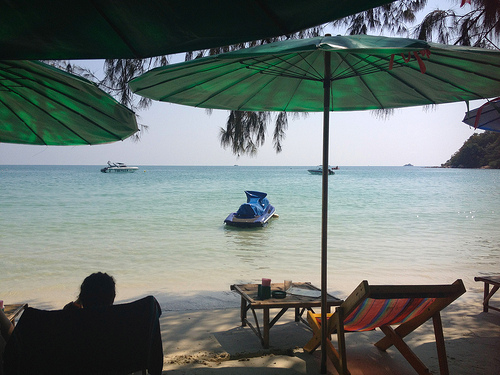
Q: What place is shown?
A: It is an ocean.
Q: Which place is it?
A: It is an ocean.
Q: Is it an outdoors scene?
A: Yes, it is outdoors.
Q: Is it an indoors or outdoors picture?
A: It is outdoors.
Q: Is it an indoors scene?
A: No, it is outdoors.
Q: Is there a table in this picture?
A: Yes, there is a table.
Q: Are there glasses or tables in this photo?
A: Yes, there is a table.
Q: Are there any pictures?
A: No, there are no pictures.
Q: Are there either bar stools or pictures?
A: No, there are no pictures or bar stools.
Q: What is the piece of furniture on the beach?
A: The piece of furniture is a table.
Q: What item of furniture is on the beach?
A: The piece of furniture is a table.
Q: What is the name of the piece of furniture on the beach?
A: The piece of furniture is a table.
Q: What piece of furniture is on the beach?
A: The piece of furniture is a table.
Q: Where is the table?
A: The table is on the beach.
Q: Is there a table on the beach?
A: Yes, there is a table on the beach.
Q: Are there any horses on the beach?
A: No, there is a table on the beach.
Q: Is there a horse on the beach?
A: No, there is a table on the beach.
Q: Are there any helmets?
A: No, there are no helmets.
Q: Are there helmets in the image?
A: No, there are no helmets.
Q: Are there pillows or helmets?
A: No, there are no helmets or pillows.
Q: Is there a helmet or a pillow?
A: No, there are no helmets or pillows.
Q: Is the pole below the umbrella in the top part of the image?
A: Yes, the pole is below the umbrella.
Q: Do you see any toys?
A: No, there are no toys.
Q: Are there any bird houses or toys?
A: No, there are no toys or bird houses.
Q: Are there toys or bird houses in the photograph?
A: No, there are no toys or bird houses.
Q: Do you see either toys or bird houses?
A: No, there are no toys or bird houses.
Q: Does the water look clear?
A: Yes, the water is clear.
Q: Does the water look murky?
A: No, the water is clear.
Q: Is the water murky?
A: No, the water is clear.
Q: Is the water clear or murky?
A: The water is clear.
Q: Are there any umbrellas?
A: Yes, there is an umbrella.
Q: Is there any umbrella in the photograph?
A: Yes, there is an umbrella.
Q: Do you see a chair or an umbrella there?
A: Yes, there is an umbrella.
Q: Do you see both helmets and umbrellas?
A: No, there is an umbrella but no helmets.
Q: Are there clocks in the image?
A: No, there are no clocks.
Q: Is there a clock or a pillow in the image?
A: No, there are no clocks or pillows.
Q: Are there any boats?
A: Yes, there is a boat.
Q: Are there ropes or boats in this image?
A: Yes, there is a boat.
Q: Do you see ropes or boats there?
A: Yes, there is a boat.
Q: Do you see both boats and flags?
A: No, there is a boat but no flags.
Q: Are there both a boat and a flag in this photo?
A: No, there is a boat but no flags.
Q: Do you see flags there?
A: No, there are no flags.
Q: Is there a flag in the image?
A: No, there are no flags.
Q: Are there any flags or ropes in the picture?
A: No, there are no flags or ropes.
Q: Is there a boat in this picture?
A: Yes, there is a boat.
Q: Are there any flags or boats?
A: Yes, there is a boat.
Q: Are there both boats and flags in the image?
A: No, there is a boat but no flags.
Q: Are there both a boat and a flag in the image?
A: No, there is a boat but no flags.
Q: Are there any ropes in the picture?
A: No, there are no ropes.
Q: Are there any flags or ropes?
A: No, there are no ropes or flags.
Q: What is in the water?
A: The boat is in the water.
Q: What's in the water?
A: The boat is in the water.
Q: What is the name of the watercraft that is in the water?
A: The watercraft is a boat.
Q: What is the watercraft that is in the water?
A: The watercraft is a boat.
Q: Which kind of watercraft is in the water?
A: The watercraft is a boat.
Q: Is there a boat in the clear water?
A: Yes, there is a boat in the water.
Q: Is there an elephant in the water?
A: No, there is a boat in the water.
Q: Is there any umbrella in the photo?
A: Yes, there is an umbrella.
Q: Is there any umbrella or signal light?
A: Yes, there is an umbrella.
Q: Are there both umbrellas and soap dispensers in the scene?
A: No, there is an umbrella but no soap dispensers.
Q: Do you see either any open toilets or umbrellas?
A: Yes, there is an open umbrella.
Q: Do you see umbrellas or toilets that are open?
A: Yes, the umbrella is open.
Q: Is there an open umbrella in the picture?
A: Yes, there is an open umbrella.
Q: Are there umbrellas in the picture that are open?
A: Yes, there is an umbrella that is open.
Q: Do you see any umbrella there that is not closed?
A: Yes, there is a open umbrella.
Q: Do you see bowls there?
A: No, there are no bowls.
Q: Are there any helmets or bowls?
A: No, there are no bowls or helmets.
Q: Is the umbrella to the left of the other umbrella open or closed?
A: The umbrella is open.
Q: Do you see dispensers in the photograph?
A: No, there are no dispensers.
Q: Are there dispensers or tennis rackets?
A: No, there are no dispensers or tennis rackets.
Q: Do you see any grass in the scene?
A: Yes, there is grass.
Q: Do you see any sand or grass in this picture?
A: Yes, there is grass.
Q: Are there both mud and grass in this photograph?
A: No, there is grass but no mud.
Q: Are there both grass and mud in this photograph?
A: No, there is grass but no mud.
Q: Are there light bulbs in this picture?
A: No, there are no light bulbs.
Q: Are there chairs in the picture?
A: Yes, there is a chair.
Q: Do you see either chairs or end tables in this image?
A: Yes, there is a chair.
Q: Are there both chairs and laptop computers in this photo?
A: No, there is a chair but no laptops.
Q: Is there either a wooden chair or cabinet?
A: Yes, there is a wood chair.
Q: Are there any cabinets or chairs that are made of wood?
A: Yes, the chair is made of wood.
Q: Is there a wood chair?
A: Yes, there is a chair that is made of wood.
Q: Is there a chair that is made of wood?
A: Yes, there is a chair that is made of wood.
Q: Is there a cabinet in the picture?
A: No, there are no cabinets.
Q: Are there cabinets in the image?
A: No, there are no cabinets.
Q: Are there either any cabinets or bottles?
A: No, there are no cabinets or bottles.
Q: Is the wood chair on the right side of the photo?
A: Yes, the chair is on the right of the image.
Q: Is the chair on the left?
A: No, the chair is on the right of the image.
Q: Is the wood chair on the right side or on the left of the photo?
A: The chair is on the right of the image.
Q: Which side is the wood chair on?
A: The chair is on the right of the image.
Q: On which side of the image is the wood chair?
A: The chair is on the right of the image.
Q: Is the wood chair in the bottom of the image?
A: Yes, the chair is in the bottom of the image.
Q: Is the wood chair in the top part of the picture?
A: No, the chair is in the bottom of the image.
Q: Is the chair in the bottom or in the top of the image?
A: The chair is in the bottom of the image.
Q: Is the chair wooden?
A: Yes, the chair is wooden.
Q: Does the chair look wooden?
A: Yes, the chair is wooden.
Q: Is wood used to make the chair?
A: Yes, the chair is made of wood.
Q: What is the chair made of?
A: The chair is made of wood.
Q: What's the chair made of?
A: The chair is made of wood.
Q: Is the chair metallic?
A: No, the chair is wooden.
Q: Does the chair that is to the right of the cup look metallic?
A: No, the chair is wooden.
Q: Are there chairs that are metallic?
A: No, there is a chair but it is wooden.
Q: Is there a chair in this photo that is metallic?
A: No, there is a chair but it is wooden.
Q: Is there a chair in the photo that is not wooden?
A: No, there is a chair but it is wooden.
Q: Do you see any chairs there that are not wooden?
A: No, there is a chair but it is wooden.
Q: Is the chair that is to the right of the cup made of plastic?
A: No, the chair is made of wood.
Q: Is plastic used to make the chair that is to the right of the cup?
A: No, the chair is made of wood.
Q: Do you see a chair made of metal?
A: No, there is a chair but it is made of wood.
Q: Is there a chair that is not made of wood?
A: No, there is a chair but it is made of wood.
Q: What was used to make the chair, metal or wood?
A: The chair is made of wood.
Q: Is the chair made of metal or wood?
A: The chair is made of wood.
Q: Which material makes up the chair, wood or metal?
A: The chair is made of wood.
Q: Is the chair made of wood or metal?
A: The chair is made of wood.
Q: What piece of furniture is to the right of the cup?
A: The piece of furniture is a chair.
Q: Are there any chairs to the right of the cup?
A: Yes, there is a chair to the right of the cup.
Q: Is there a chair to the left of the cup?
A: No, the chair is to the right of the cup.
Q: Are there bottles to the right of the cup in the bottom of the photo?
A: No, there is a chair to the right of the cup.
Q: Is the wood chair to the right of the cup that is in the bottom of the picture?
A: Yes, the chair is to the right of the cup.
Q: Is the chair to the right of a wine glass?
A: No, the chair is to the right of the cup.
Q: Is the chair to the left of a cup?
A: No, the chair is to the right of a cup.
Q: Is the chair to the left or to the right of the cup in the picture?
A: The chair is to the right of the cup.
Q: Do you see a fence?
A: No, there are no fences.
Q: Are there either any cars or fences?
A: No, there are no fences or cars.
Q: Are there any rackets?
A: No, there are no rackets.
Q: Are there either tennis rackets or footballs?
A: No, there are no tennis rackets or footballs.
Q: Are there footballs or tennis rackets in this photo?
A: No, there are no tennis rackets or footballs.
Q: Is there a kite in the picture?
A: No, there are no kites.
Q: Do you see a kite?
A: No, there are no kites.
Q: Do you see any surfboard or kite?
A: No, there are no kites or surfboards.